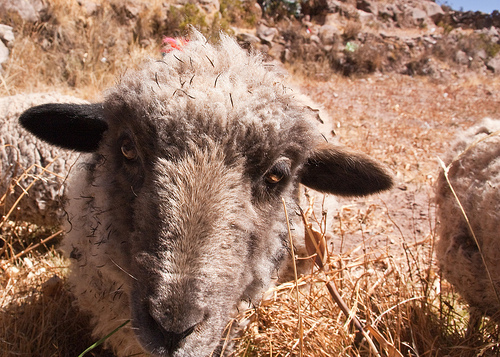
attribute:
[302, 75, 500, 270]
ground — present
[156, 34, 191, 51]
hair — pink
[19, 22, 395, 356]
sheep — large, facing, staring, white, gray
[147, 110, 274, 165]
wool — brown, black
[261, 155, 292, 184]
eye — gold, black, golden, open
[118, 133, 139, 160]
eye — gold, black, golden, open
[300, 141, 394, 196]
ear — black, extended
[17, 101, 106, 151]
ear — black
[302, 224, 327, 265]
leaf — gold, brown, hanging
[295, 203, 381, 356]
branch — sticking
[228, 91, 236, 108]
strand — black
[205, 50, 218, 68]
strand — black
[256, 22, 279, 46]
stone — tan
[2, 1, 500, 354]
field — present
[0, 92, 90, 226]
sheep — furry, white, present, sitting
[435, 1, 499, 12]
sky — blue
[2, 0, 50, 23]
rock — present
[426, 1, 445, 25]
rock — present, big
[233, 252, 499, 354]
grass — brown, dry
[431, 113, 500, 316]
sheep — present, rough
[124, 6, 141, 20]
rock — present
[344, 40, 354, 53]
foliage — green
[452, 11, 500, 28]
trees — present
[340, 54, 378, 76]
shrub — vegetation, hardy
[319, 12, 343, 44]
rock — big